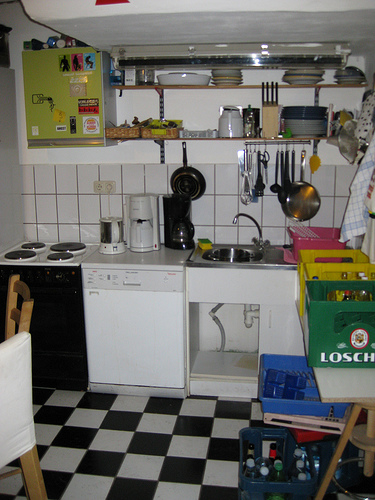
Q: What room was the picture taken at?
A: It was taken at the kitchen.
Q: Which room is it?
A: It is a kitchen.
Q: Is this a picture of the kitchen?
A: Yes, it is showing the kitchen.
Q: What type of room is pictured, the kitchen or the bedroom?
A: It is the kitchen.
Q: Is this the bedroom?
A: No, it is the kitchen.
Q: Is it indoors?
A: Yes, it is indoors.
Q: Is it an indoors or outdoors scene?
A: It is indoors.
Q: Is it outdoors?
A: No, it is indoors.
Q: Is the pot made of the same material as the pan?
A: Yes, both the pot and the pan are made of metal.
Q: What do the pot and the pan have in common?
A: The material, both the pot and the pan are metallic.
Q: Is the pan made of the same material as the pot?
A: Yes, both the pan and the pot are made of metal.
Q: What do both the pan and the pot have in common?
A: The material, both the pan and the pot are metallic.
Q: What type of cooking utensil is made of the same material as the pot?
A: The pan is made of the same material as the pot.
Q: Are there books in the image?
A: No, there are no books.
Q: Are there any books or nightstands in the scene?
A: No, there are no books or nightstands.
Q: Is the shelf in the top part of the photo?
A: Yes, the shelf is in the top of the image.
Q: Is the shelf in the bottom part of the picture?
A: No, the shelf is in the top of the image.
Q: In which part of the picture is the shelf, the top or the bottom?
A: The shelf is in the top of the image.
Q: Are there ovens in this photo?
A: Yes, there is an oven.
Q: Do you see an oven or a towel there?
A: Yes, there is an oven.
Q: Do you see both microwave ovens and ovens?
A: No, there is an oven but no microwave ovens.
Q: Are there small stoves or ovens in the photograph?
A: Yes, there is a small oven.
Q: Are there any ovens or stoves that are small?
A: Yes, the oven is small.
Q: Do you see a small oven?
A: Yes, there is a small oven.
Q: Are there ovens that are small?
A: Yes, there is an oven that is small.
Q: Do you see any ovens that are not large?
A: Yes, there is a small oven.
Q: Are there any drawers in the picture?
A: No, there are no drawers.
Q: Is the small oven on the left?
A: Yes, the oven is on the left of the image.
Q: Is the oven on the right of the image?
A: No, the oven is on the left of the image.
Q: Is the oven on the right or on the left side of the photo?
A: The oven is on the left of the image.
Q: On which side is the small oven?
A: The oven is on the left of the image.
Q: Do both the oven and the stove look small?
A: Yes, both the oven and the stove are small.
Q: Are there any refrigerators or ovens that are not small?
A: No, there is an oven but it is small.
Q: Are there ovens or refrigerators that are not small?
A: No, there is an oven but it is small.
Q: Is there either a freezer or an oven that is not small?
A: No, there is an oven but it is small.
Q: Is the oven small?
A: Yes, the oven is small.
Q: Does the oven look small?
A: Yes, the oven is small.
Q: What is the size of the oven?
A: The oven is small.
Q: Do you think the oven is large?
A: No, the oven is small.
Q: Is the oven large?
A: No, the oven is small.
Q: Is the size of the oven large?
A: No, the oven is small.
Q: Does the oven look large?
A: No, the oven is small.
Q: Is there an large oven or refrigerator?
A: No, there is an oven but it is small.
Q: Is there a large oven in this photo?
A: No, there is an oven but it is small.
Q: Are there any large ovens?
A: No, there is an oven but it is small.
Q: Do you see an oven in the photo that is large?
A: No, there is an oven but it is small.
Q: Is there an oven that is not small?
A: No, there is an oven but it is small.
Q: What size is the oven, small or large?
A: The oven is small.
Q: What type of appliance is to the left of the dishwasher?
A: The appliance is an oven.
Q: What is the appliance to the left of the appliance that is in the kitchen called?
A: The appliance is an oven.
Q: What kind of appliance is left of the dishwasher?
A: The appliance is an oven.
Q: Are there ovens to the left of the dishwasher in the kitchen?
A: Yes, there is an oven to the left of the dishwasher.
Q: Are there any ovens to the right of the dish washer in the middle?
A: No, the oven is to the left of the dishwasher.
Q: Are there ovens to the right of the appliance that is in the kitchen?
A: No, the oven is to the left of the dishwasher.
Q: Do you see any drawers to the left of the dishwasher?
A: No, there is an oven to the left of the dishwasher.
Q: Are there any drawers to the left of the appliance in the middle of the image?
A: No, there is an oven to the left of the dishwasher.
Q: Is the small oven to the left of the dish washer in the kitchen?
A: Yes, the oven is to the left of the dishwasher.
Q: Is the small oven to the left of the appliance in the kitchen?
A: Yes, the oven is to the left of the dishwasher.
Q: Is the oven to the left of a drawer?
A: No, the oven is to the left of the dishwasher.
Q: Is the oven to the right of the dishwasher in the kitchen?
A: No, the oven is to the left of the dishwasher.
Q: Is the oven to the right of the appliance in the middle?
A: No, the oven is to the left of the dishwasher.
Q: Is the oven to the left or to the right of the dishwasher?
A: The oven is to the left of the dishwasher.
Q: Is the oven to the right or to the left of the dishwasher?
A: The oven is to the left of the dishwasher.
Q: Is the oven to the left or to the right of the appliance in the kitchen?
A: The oven is to the left of the dishwasher.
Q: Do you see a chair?
A: Yes, there is a chair.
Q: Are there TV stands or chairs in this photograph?
A: Yes, there is a chair.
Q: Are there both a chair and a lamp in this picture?
A: No, there is a chair but no lamps.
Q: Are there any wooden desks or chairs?
A: Yes, there is a wood chair.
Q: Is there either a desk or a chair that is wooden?
A: Yes, the chair is wooden.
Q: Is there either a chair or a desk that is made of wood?
A: Yes, the chair is made of wood.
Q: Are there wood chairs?
A: Yes, there is a chair that is made of wood.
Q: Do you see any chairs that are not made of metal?
A: Yes, there is a chair that is made of wood.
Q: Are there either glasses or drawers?
A: No, there are no drawers or glasses.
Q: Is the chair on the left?
A: Yes, the chair is on the left of the image.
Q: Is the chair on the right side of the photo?
A: No, the chair is on the left of the image.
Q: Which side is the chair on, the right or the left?
A: The chair is on the left of the image.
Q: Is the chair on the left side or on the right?
A: The chair is on the left of the image.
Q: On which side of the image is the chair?
A: The chair is on the left of the image.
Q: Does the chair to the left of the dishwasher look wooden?
A: Yes, the chair is wooden.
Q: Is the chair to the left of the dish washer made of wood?
A: Yes, the chair is made of wood.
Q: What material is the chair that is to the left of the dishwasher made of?
A: The chair is made of wood.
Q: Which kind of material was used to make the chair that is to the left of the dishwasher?
A: The chair is made of wood.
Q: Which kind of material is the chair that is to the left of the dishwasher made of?
A: The chair is made of wood.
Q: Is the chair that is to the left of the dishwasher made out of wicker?
A: No, the chair is made of wood.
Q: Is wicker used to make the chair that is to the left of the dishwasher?
A: No, the chair is made of wood.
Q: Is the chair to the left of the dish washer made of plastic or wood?
A: The chair is made of wood.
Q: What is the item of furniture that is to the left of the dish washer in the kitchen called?
A: The piece of furniture is a chair.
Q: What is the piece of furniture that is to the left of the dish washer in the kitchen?
A: The piece of furniture is a chair.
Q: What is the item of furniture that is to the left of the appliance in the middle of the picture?
A: The piece of furniture is a chair.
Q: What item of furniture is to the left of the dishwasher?
A: The piece of furniture is a chair.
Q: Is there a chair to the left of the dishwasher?
A: Yes, there is a chair to the left of the dishwasher.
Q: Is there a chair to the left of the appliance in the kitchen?
A: Yes, there is a chair to the left of the dishwasher.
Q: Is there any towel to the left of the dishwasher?
A: No, there is a chair to the left of the dishwasher.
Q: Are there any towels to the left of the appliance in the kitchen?
A: No, there is a chair to the left of the dishwasher.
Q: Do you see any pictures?
A: No, there are no pictures.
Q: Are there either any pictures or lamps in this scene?
A: No, there are no pictures or lamps.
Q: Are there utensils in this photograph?
A: Yes, there are utensils.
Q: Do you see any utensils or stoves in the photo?
A: Yes, there are utensils.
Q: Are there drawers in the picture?
A: No, there are no drawers.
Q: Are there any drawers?
A: No, there are no drawers.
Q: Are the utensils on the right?
A: Yes, the utensils are on the right of the image.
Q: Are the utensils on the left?
A: No, the utensils are on the right of the image.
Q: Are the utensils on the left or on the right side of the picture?
A: The utensils are on the right of the image.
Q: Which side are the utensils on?
A: The utensils are on the right of the image.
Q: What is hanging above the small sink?
A: The utensils are hanging above the sink.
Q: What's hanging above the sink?
A: The utensils are hanging above the sink.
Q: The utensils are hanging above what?
A: The utensils are hanging above the sink.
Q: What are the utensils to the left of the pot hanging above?
A: The utensils are hanging above the sink.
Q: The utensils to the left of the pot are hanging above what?
A: The utensils are hanging above the sink.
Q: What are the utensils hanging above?
A: The utensils are hanging above the sink.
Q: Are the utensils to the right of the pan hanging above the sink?
A: Yes, the utensils are hanging above the sink.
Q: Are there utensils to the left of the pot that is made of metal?
A: Yes, there are utensils to the left of the pot.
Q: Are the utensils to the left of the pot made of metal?
A: Yes, the utensils are to the left of the pot.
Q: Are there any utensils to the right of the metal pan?
A: Yes, there are utensils to the right of the pan.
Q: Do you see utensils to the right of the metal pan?
A: Yes, there are utensils to the right of the pan.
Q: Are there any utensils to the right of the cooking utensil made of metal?
A: Yes, there are utensils to the right of the pan.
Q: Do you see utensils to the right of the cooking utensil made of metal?
A: Yes, there are utensils to the right of the pan.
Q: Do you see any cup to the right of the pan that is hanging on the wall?
A: No, there are utensils to the right of the pan.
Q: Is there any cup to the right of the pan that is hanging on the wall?
A: No, there are utensils to the right of the pan.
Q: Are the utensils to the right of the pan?
A: Yes, the utensils are to the right of the pan.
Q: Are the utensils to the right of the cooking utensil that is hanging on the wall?
A: Yes, the utensils are to the right of the pan.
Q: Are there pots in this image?
A: Yes, there is a pot.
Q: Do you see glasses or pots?
A: Yes, there is a pot.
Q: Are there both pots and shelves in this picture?
A: Yes, there are both a pot and a shelf.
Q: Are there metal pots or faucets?
A: Yes, there is a metal pot.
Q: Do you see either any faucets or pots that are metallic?
A: Yes, the pot is metallic.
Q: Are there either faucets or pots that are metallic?
A: Yes, the pot is metallic.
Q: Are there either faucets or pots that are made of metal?
A: Yes, the pot is made of metal.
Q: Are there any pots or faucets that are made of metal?
A: Yes, the pot is made of metal.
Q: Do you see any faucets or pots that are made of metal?
A: Yes, the pot is made of metal.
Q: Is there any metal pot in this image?
A: Yes, there is a metal pot.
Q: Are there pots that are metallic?
A: Yes, there is a pot that is metallic.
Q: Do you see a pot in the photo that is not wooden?
A: Yes, there is a metallic pot.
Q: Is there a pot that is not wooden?
A: Yes, there is a metallic pot.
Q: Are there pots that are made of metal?
A: Yes, there is a pot that is made of metal.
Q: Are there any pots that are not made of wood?
A: Yes, there is a pot that is made of metal.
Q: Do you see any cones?
A: No, there are no cones.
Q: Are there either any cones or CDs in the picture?
A: No, there are no cones or cds.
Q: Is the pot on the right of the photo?
A: Yes, the pot is on the right of the image.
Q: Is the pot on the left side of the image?
A: No, the pot is on the right of the image.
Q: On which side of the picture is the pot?
A: The pot is on the right of the image.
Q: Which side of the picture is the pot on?
A: The pot is on the right of the image.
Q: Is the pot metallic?
A: Yes, the pot is metallic.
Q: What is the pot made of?
A: The pot is made of metal.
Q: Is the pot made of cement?
A: No, the pot is made of metal.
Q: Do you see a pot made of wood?
A: No, there is a pot but it is made of metal.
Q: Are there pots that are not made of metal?
A: No, there is a pot but it is made of metal.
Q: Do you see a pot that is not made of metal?
A: No, there is a pot but it is made of metal.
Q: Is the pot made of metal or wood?
A: The pot is made of metal.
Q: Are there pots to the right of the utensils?
A: Yes, there is a pot to the right of the utensils.